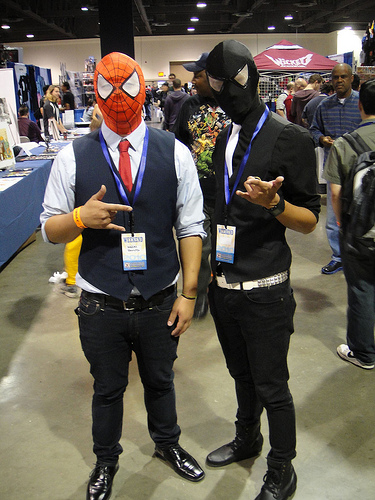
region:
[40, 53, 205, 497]
a man wearing red color mask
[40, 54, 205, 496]
a guy wearing spider man mask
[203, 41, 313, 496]
a man wearing white color waist belt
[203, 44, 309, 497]
a guy with blue color tag around his neck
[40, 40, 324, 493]
two men gesturing with their hands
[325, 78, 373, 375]
a man standing with his back pack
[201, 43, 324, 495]
a man wearing black color mask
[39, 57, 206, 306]
a man with yellow color wrist band in his right hand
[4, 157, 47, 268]
a table covered with blue color cloth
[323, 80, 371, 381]
a guy with his left hand in his pant pocket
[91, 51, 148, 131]
The person is wearing a Spiderman mask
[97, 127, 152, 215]
The lanyard is blue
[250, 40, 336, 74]
The tent is red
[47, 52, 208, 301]
The person is wearing a black vest with a white shirt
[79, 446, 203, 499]
The shoes are shiny black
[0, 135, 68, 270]
The booth cloth is blue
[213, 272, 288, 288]
The belt is white with silver studs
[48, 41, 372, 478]
The people are inside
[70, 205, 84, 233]
The arm band is orange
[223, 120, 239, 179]
The person is wearing a white tie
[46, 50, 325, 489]
two men wearing superhero masks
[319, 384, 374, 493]
grey concrete surface of the sidewalk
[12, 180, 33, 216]
blue tablecloth over the table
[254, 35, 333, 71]
red canopy of a tent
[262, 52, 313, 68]
white logo on a red canopy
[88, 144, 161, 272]
a tag on a lanyard around a person's neck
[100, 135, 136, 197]
the red neck tie of the man on the left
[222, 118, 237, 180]
the white neck tie of the man on the right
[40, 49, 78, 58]
white wall of the room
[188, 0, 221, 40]
white lights hanging from the ceiling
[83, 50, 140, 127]
A spider web mask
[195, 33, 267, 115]
A black mask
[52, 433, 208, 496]
Black shoes in the photo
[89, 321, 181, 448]
Black jeans in the photo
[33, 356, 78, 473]
A floor in the room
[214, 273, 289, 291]
White belt in the photo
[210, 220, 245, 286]
A tag in the photo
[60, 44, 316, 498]
Two men standing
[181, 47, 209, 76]
A cap in the photo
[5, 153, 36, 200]
A table in the photo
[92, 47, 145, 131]
Orange spiderman facial mask.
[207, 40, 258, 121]
Black spiderman's facial mask.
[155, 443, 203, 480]
Man's right dress shoe.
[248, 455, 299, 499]
Man's black colored boot.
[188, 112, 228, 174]
Colorful design on man's shirt.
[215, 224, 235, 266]
Blue and white name tag.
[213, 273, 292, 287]
Man's white metal studded belt.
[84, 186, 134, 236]
Man's hand in spiderman's position.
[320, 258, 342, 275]
Blue and black man's tennis shoe.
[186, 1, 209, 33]
Three inner ceiling lights.